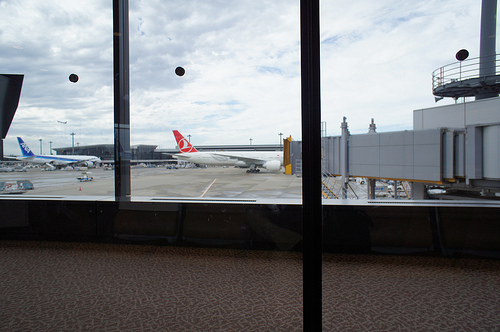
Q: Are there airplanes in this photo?
A: Yes, there is an airplane.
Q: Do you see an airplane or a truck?
A: Yes, there is an airplane.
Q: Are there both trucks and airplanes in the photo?
A: No, there is an airplane but no trucks.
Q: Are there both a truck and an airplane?
A: No, there is an airplane but no trucks.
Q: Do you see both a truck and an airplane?
A: No, there is an airplane but no trucks.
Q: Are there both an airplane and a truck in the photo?
A: No, there is an airplane but no trucks.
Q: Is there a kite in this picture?
A: No, there are no kites.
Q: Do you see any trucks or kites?
A: No, there are no kites or trucks.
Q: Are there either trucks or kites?
A: No, there are no kites or trucks.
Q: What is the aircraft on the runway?
A: The aircraft is an airplane.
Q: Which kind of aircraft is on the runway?
A: The aircraft is an airplane.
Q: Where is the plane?
A: The plane is on the runway.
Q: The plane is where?
A: The plane is on the runway.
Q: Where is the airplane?
A: The plane is on the runway.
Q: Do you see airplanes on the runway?
A: Yes, there is an airplane on the runway.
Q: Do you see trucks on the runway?
A: No, there is an airplane on the runway.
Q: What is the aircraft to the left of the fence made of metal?
A: The aircraft is an airplane.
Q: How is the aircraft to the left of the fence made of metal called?
A: The aircraft is an airplane.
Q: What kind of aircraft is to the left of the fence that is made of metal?
A: The aircraft is an airplane.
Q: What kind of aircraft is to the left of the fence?
A: The aircraft is an airplane.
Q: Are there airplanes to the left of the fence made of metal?
A: Yes, there is an airplane to the left of the fence.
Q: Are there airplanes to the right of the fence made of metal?
A: No, the airplane is to the left of the fence.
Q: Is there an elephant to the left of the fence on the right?
A: No, there is an airplane to the left of the fence.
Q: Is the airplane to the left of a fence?
A: Yes, the airplane is to the left of a fence.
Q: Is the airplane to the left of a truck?
A: No, the airplane is to the left of a fence.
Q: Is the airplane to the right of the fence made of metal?
A: No, the airplane is to the left of the fence.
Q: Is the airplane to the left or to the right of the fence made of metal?
A: The airplane is to the left of the fence.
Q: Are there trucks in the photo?
A: No, there are no trucks.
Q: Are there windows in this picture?
A: Yes, there is a window.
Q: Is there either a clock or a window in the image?
A: Yes, there is a window.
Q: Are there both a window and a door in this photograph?
A: No, there is a window but no doors.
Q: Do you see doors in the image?
A: No, there are no doors.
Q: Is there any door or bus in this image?
A: No, there are no doors or buses.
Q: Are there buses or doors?
A: No, there are no doors or buses.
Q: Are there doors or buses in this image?
A: No, there are no doors or buses.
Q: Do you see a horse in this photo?
A: No, there are no horses.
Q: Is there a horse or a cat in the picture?
A: No, there are no horses or cats.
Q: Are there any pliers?
A: No, there are no pliers.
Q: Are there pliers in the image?
A: No, there are no pliers.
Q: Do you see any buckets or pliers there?
A: No, there are no pliers or buckets.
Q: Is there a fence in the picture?
A: Yes, there is a fence.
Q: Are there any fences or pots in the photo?
A: Yes, there is a fence.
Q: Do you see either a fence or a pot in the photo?
A: Yes, there is a fence.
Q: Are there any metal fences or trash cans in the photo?
A: Yes, there is a metal fence.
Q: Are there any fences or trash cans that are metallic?
A: Yes, the fence is metallic.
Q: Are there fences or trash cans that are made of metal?
A: Yes, the fence is made of metal.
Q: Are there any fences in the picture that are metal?
A: Yes, there is a metal fence.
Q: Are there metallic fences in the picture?
A: Yes, there is a metal fence.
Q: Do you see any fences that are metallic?
A: Yes, there is a fence that is metallic.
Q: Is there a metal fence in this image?
A: Yes, there is a fence that is made of metal.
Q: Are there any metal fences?
A: Yes, there is a fence that is made of metal.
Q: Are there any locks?
A: No, there are no locks.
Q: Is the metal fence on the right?
A: Yes, the fence is on the right of the image.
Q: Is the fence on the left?
A: No, the fence is on the right of the image.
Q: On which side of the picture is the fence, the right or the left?
A: The fence is on the right of the image.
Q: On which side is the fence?
A: The fence is on the right of the image.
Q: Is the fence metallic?
A: Yes, the fence is metallic.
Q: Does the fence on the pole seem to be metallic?
A: Yes, the fence is metallic.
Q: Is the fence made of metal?
A: Yes, the fence is made of metal.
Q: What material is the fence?
A: The fence is made of metal.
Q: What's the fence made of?
A: The fence is made of metal.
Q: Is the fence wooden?
A: No, the fence is metallic.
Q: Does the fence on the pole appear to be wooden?
A: No, the fence is metallic.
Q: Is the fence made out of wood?
A: No, the fence is made of metal.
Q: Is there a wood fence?
A: No, there is a fence but it is made of metal.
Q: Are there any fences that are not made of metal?
A: No, there is a fence but it is made of metal.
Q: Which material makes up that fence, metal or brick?
A: The fence is made of metal.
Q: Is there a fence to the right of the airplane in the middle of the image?
A: Yes, there is a fence to the right of the airplane.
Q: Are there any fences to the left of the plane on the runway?
A: No, the fence is to the right of the airplane.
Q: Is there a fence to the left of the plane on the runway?
A: No, the fence is to the right of the airplane.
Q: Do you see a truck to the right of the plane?
A: No, there is a fence to the right of the plane.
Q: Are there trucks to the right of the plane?
A: No, there is a fence to the right of the plane.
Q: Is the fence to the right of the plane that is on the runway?
A: Yes, the fence is to the right of the airplane.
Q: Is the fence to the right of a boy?
A: No, the fence is to the right of the airplane.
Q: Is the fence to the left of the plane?
A: No, the fence is to the right of the plane.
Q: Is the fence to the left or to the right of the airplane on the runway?
A: The fence is to the right of the airplane.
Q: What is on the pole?
A: The fence is on the pole.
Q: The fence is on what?
A: The fence is on the pole.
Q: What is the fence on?
A: The fence is on the pole.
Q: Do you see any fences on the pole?
A: Yes, there is a fence on the pole.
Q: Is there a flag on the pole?
A: No, there is a fence on the pole.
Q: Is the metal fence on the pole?
A: Yes, the fence is on the pole.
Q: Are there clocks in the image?
A: No, there are no clocks.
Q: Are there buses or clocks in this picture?
A: No, there are no clocks or buses.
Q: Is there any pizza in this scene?
A: No, there are no pizzas.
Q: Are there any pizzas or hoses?
A: No, there are no pizzas or hoses.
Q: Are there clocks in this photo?
A: No, there are no clocks.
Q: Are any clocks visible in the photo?
A: No, there are no clocks.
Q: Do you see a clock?
A: No, there are no clocks.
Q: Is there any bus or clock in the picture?
A: No, there are no clocks or buses.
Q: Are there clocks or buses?
A: No, there are no clocks or buses.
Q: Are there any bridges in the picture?
A: Yes, there is a bridge.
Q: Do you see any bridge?
A: Yes, there is a bridge.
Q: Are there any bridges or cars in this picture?
A: Yes, there is a bridge.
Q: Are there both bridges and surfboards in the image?
A: No, there is a bridge but no surfboards.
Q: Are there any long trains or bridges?
A: Yes, there is a long bridge.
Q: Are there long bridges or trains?
A: Yes, there is a long bridge.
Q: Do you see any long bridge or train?
A: Yes, there is a long bridge.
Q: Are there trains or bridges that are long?
A: Yes, the bridge is long.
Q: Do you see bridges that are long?
A: Yes, there is a long bridge.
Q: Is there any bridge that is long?
A: Yes, there is a bridge that is long.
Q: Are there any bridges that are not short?
A: Yes, there is a long bridge.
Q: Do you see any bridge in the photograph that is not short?
A: Yes, there is a long bridge.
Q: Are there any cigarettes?
A: No, there are no cigarettes.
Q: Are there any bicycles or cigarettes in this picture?
A: No, there are no cigarettes or bicycles.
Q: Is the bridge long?
A: Yes, the bridge is long.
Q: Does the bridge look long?
A: Yes, the bridge is long.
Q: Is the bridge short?
A: No, the bridge is long.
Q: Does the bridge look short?
A: No, the bridge is long.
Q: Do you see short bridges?
A: No, there is a bridge but it is long.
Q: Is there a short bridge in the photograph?
A: No, there is a bridge but it is long.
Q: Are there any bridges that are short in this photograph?
A: No, there is a bridge but it is long.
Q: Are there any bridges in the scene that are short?
A: No, there is a bridge but it is long.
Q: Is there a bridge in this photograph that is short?
A: No, there is a bridge but it is long.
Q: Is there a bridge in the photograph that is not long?
A: No, there is a bridge but it is long.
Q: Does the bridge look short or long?
A: The bridge is long.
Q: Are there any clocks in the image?
A: No, there are no clocks.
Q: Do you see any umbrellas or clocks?
A: No, there are no clocks or umbrellas.